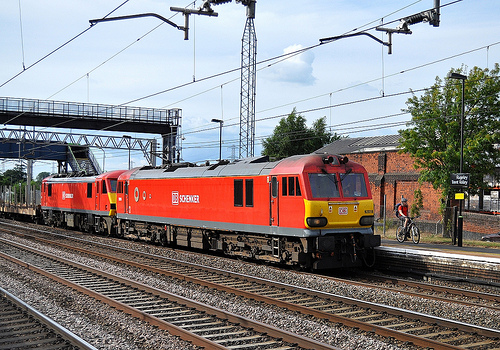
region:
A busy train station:
[7, 0, 494, 349]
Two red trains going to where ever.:
[32, 154, 397, 249]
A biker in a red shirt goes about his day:
[388, 191, 440, 251]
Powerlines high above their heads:
[0, 0, 497, 119]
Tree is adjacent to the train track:
[382, 71, 499, 232]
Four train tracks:
[1, 210, 467, 348]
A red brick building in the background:
[310, 125, 470, 225]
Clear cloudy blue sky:
[0, 0, 492, 155]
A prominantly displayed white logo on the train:
[167, 190, 210, 210]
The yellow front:
[297, 200, 382, 226]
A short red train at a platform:
[40, 152, 378, 269]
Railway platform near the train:
[376, 235, 496, 272]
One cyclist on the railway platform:
[393, 198, 420, 244]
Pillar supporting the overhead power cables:
[240, 0, 254, 159]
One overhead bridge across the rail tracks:
[0, 95, 182, 162]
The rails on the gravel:
[0, 218, 497, 349]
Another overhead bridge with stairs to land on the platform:
[0, 140, 101, 174]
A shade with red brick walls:
[317, 136, 450, 233]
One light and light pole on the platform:
[451, 73, 464, 245]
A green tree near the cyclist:
[400, 65, 498, 242]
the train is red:
[11, 155, 388, 270]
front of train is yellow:
[304, 193, 387, 243]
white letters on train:
[155, 184, 222, 217]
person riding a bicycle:
[385, 186, 422, 251]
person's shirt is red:
[386, 201, 411, 222]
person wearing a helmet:
[387, 187, 409, 209]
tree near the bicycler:
[405, 73, 493, 244]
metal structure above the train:
[0, 1, 498, 113]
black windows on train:
[26, 179, 114, 206]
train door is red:
[252, 169, 287, 232]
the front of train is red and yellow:
[298, 158, 380, 258]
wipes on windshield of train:
[300, 161, 375, 201]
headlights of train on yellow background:
[306, 208, 377, 227]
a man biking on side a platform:
[386, 186, 426, 250]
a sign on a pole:
[443, 163, 475, 244]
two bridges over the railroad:
[3, 92, 192, 167]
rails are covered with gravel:
[18, 249, 480, 344]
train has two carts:
[29, 148, 396, 277]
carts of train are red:
[29, 143, 379, 265]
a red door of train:
[258, 165, 285, 233]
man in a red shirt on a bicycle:
[394, 193, 422, 246]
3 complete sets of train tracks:
[104, 261, 499, 348]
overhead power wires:
[90, 0, 475, 97]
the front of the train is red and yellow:
[300, 160, 375, 227]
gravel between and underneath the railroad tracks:
[45, 265, 485, 345]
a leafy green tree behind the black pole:
[415, 65, 495, 230]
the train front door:
[261, 171, 282, 226]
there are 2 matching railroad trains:
[35, 140, 390, 260]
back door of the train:
[116, 177, 133, 212]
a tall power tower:
[230, 0, 263, 160]